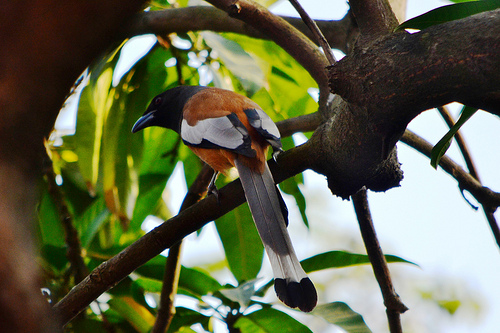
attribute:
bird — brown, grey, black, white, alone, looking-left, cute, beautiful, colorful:
[132, 83, 320, 310]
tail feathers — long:
[237, 150, 318, 310]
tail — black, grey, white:
[234, 157, 318, 315]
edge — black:
[275, 275, 317, 312]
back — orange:
[184, 84, 260, 120]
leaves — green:
[142, 204, 392, 327]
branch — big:
[248, 13, 498, 189]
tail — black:
[268, 270, 320, 310]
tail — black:
[272, 271, 322, 312]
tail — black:
[272, 275, 320, 315]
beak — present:
[128, 111, 154, 135]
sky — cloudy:
[283, 125, 499, 331]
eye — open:
[148, 94, 171, 118]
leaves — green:
[57, 30, 390, 331]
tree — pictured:
[7, 6, 499, 331]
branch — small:
[343, 174, 423, 331]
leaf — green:
[191, 163, 268, 302]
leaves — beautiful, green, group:
[54, 35, 346, 331]